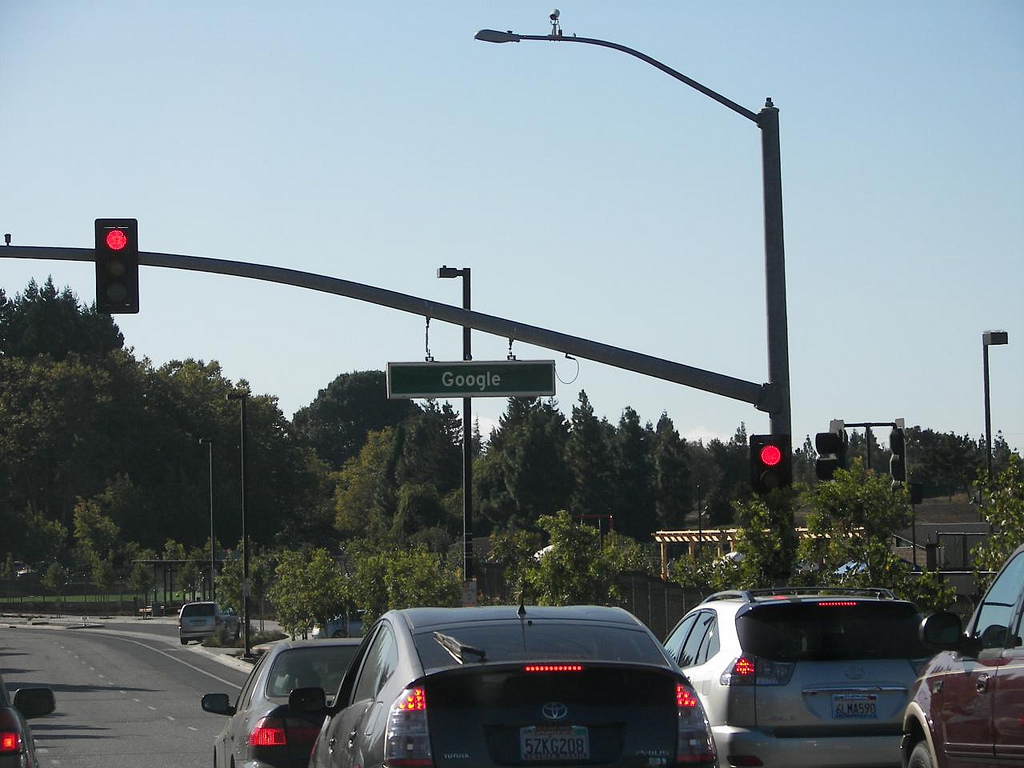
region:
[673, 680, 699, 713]
car has a light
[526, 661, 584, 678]
car has a light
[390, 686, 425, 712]
car has a light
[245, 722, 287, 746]
car has a light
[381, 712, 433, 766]
car has a light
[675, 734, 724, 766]
car has a light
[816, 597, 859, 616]
car has a light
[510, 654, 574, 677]
light on the car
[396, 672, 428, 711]
light on the car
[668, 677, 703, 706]
light on the car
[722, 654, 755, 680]
light on the car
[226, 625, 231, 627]
light on the car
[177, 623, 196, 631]
light on the car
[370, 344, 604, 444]
green and white street sign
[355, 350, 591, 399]
green and white street sign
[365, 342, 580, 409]
green and white street sign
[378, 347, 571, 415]
green and white street sign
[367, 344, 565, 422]
green and white street sign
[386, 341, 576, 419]
green and white street sign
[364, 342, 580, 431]
green and white street sign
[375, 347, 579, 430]
green and white street sign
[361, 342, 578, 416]
green and white street sign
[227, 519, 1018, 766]
a group of cars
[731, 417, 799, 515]
a black traffic light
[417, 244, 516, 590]
light on a pole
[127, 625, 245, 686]
line on the side of the road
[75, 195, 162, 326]
light is lit red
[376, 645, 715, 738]
break lights on a car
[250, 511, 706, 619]
bushes next to street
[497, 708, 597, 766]
license plate on the car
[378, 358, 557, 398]
Street sign on a post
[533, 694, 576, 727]
Logo on a car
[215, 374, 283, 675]
Street light by a road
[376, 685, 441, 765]
Light on the back of a car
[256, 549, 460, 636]
Trees by a road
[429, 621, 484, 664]
Wiper blade on a car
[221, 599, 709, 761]
Cars at a stop light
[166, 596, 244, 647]
Car turning on a road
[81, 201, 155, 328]
A traffic light is lit red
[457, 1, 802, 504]
A tall street lamp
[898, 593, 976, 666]
A side mirror of a car